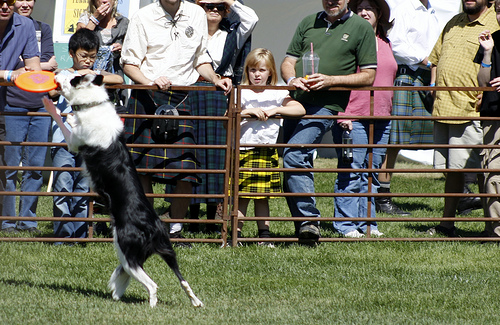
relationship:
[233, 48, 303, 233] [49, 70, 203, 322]
person watching dog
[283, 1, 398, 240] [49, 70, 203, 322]
person watching dog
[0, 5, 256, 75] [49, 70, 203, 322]
person watching dog